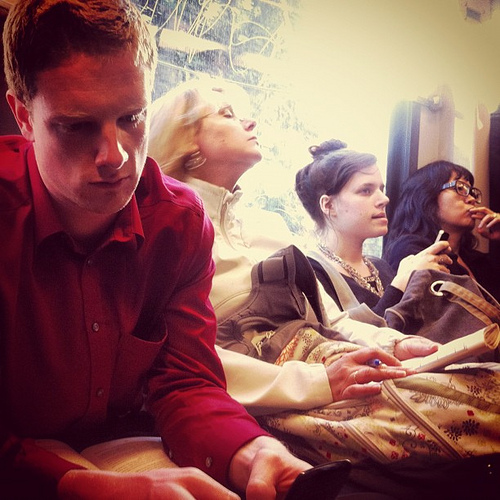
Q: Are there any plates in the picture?
A: No, there are no plates.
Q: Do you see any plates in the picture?
A: No, there are no plates.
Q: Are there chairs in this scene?
A: No, there are no chairs.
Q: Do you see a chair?
A: No, there are no chairs.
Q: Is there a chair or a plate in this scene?
A: No, there are no chairs or plates.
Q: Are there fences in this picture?
A: No, there are no fences.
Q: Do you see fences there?
A: No, there are no fences.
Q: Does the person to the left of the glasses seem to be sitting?
A: Yes, the person is sitting.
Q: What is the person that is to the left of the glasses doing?
A: The person is sitting.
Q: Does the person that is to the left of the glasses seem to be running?
A: No, the person is sitting.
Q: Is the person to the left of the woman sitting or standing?
A: The person is sitting.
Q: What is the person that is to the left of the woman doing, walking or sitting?
A: The person is sitting.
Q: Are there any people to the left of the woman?
A: Yes, there is a person to the left of the woman.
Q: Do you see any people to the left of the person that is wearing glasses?
A: Yes, there is a person to the left of the woman.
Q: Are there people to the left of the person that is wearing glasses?
A: Yes, there is a person to the left of the woman.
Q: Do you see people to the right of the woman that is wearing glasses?
A: No, the person is to the left of the woman.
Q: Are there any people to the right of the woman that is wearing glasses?
A: No, the person is to the left of the woman.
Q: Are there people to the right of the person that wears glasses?
A: No, the person is to the left of the woman.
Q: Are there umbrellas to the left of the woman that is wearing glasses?
A: No, there is a person to the left of the woman.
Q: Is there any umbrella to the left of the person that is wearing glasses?
A: No, there is a person to the left of the woman.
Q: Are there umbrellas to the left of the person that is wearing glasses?
A: No, there is a person to the left of the woman.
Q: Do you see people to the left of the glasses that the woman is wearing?
A: Yes, there is a person to the left of the glasses.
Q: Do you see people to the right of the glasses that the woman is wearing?
A: No, the person is to the left of the glasses.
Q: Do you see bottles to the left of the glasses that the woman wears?
A: No, there is a person to the left of the glasses.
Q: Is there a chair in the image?
A: No, there are no chairs.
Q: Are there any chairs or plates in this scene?
A: No, there are no chairs or plates.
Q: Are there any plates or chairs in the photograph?
A: No, there are no chairs or plates.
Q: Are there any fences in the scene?
A: No, there are no fences.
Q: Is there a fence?
A: No, there are no fences.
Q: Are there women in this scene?
A: Yes, there is a woman.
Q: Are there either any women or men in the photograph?
A: Yes, there is a woman.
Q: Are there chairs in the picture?
A: No, there are no chairs.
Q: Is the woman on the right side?
A: Yes, the woman is on the right of the image.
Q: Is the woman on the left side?
A: No, the woman is on the right of the image.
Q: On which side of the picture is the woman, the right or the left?
A: The woman is on the right of the image.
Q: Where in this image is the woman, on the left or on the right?
A: The woman is on the right of the image.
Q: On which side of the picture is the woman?
A: The woman is on the right of the image.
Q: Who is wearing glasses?
A: The woman is wearing glasses.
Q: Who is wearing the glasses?
A: The woman is wearing glasses.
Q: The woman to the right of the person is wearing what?
A: The woman is wearing glasses.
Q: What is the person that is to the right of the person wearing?
A: The woman is wearing glasses.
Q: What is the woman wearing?
A: The woman is wearing glasses.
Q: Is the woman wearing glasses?
A: Yes, the woman is wearing glasses.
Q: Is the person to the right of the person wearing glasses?
A: Yes, the woman is wearing glasses.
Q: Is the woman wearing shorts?
A: No, the woman is wearing glasses.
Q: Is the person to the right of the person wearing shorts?
A: No, the woman is wearing glasses.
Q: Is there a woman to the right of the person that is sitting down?
A: Yes, there is a woman to the right of the person.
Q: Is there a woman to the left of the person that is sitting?
A: No, the woman is to the right of the person.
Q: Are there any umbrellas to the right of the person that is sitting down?
A: No, there is a woman to the right of the person.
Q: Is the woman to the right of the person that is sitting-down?
A: Yes, the woman is to the right of the person.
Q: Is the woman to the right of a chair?
A: No, the woman is to the right of the person.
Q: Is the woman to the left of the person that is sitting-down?
A: No, the woman is to the right of the person.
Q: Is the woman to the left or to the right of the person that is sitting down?
A: The woman is to the right of the person.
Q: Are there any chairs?
A: No, there are no chairs.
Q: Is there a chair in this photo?
A: No, there are no chairs.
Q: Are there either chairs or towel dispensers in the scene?
A: No, there are no chairs or towel dispensers.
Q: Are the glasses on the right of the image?
A: Yes, the glasses are on the right of the image.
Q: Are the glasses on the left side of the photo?
A: No, the glasses are on the right of the image.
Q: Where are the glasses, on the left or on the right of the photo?
A: The glasses are on the right of the image.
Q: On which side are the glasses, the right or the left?
A: The glasses are on the right of the image.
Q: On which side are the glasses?
A: The glasses are on the right of the image.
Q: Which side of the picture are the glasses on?
A: The glasses are on the right of the image.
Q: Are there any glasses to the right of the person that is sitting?
A: Yes, there are glasses to the right of the person.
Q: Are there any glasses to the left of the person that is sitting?
A: No, the glasses are to the right of the person.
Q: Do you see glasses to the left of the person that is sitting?
A: No, the glasses are to the right of the person.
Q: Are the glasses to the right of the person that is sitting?
A: Yes, the glasses are to the right of the person.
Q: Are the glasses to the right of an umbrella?
A: No, the glasses are to the right of the person.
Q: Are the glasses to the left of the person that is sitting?
A: No, the glasses are to the right of the person.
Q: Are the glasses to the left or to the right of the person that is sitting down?
A: The glasses are to the right of the person.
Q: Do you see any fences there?
A: No, there are no fences.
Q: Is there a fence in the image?
A: No, there are no fences.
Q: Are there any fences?
A: No, there are no fences.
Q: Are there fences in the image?
A: No, there are no fences.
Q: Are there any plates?
A: No, there are no plates.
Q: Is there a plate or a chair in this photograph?
A: No, there are no plates or chairs.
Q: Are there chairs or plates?
A: No, there are no plates or chairs.